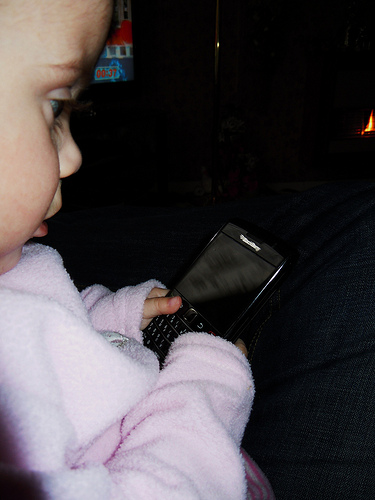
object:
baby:
[0, 2, 256, 498]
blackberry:
[128, 224, 284, 369]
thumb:
[140, 293, 182, 316]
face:
[0, 0, 113, 250]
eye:
[45, 87, 73, 126]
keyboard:
[141, 310, 188, 354]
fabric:
[3, 320, 74, 441]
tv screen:
[87, 3, 136, 85]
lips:
[38, 193, 65, 246]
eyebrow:
[47, 54, 95, 76]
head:
[0, 0, 106, 278]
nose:
[49, 114, 87, 184]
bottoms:
[235, 442, 269, 497]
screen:
[183, 230, 259, 315]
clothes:
[1, 248, 253, 498]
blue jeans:
[254, 197, 375, 494]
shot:
[0, 0, 375, 500]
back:
[137, 0, 362, 193]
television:
[76, 26, 144, 90]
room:
[0, 0, 375, 500]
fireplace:
[343, 92, 375, 141]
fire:
[357, 113, 375, 148]